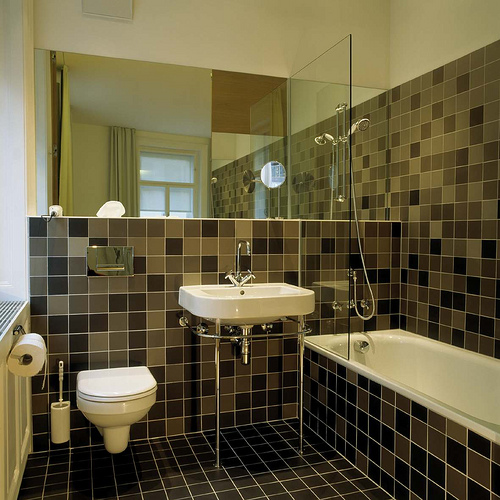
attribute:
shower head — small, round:
[326, 110, 376, 148]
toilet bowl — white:
[71, 389, 157, 429]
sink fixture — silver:
[222, 239, 258, 290]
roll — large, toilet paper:
[9, 326, 43, 376]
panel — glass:
[292, 37, 348, 380]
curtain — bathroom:
[108, 125, 136, 217]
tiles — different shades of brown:
[388, 58, 486, 348]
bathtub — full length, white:
[302, 313, 486, 478]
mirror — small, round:
[260, 158, 285, 188]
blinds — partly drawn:
[140, 150, 196, 210]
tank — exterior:
[82, 305, 162, 367]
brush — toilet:
[48, 359, 73, 445]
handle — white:
[52, 358, 64, 399]